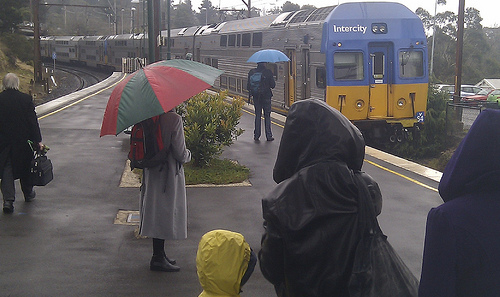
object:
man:
[246, 58, 276, 142]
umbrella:
[246, 48, 291, 64]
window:
[334, 50, 365, 81]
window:
[398, 49, 426, 78]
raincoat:
[257, 96, 383, 295]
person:
[252, 94, 424, 297]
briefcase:
[30, 149, 55, 186]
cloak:
[417, 105, 499, 295]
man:
[0, 67, 50, 213]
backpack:
[246, 68, 271, 105]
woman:
[123, 97, 199, 274]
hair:
[3, 72, 20, 91]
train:
[28, 0, 436, 150]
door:
[287, 49, 296, 106]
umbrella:
[97, 58, 225, 138]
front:
[318, 0, 435, 130]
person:
[414, 101, 500, 292]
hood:
[189, 229, 252, 291]